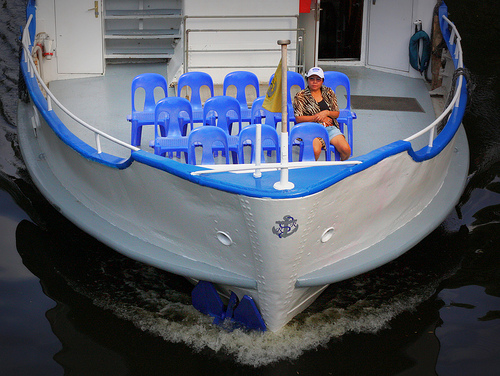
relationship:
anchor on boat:
[190, 280, 266, 334] [20, 4, 470, 334]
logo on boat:
[272, 215, 298, 237] [20, 4, 470, 334]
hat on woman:
[303, 65, 323, 79] [292, 65, 356, 160]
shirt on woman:
[289, 73, 352, 137] [282, 58, 366, 175]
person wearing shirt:
[293, 67, 351, 161] [292, 85, 339, 115]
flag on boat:
[261, 59, 283, 114] [20, 4, 470, 334]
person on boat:
[295, 64, 360, 162] [20, 4, 470, 334]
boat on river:
[20, 4, 470, 334] [2, 2, 497, 373]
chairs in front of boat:
[128, 71, 352, 160] [18, 0, 471, 334]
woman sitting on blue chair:
[292, 67, 350, 162] [289, 117, 341, 167]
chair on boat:
[237, 123, 280, 164] [20, 4, 470, 334]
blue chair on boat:
[125, 72, 170, 146] [20, 4, 470, 334]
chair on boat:
[153, 96, 193, 165] [20, 4, 470, 334]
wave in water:
[82, 275, 439, 362] [0, 0, 499, 374]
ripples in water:
[52, 248, 468, 371] [0, 0, 499, 374]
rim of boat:
[14, 18, 466, 210] [17, 9, 472, 247]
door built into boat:
[313, 1, 365, 63] [20, 4, 470, 334]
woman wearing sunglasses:
[292, 65, 356, 160] [307, 75, 322, 82]